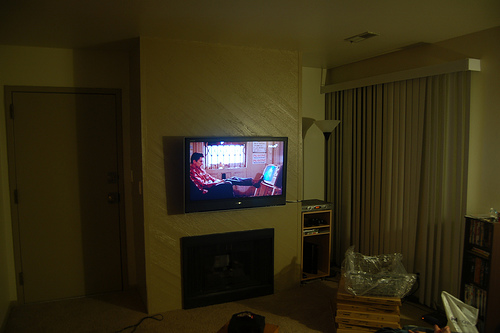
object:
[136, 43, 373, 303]
wall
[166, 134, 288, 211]
televeision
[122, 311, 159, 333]
cable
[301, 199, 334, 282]
shelf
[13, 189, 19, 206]
hinges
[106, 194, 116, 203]
door knob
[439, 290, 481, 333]
bag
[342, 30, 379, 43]
air vent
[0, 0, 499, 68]
ceiling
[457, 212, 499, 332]
shelf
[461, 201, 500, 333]
items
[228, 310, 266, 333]
object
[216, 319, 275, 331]
table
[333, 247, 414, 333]
boxes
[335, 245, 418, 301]
packaging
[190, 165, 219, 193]
shirt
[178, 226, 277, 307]
fireplace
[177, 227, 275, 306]
square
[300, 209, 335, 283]
entertainment center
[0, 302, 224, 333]
floor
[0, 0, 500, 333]
room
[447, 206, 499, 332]
folded paper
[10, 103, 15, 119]
hinge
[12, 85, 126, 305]
door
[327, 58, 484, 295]
blinds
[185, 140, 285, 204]
screen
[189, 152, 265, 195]
man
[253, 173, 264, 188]
foot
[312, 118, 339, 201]
lamp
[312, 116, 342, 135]
shade